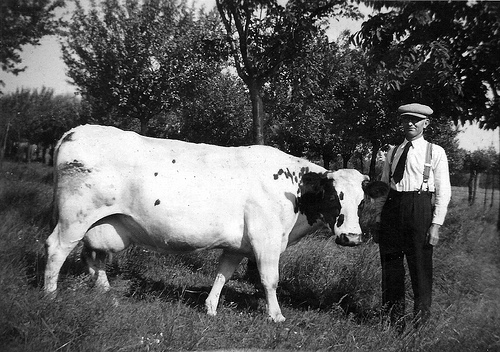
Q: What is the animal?
A: Cow.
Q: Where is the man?
A: Right of the cow.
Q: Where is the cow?
A: Left of the man.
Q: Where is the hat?
A: Man's head.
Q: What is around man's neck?
A: Black tie.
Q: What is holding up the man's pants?
A: Suspenders.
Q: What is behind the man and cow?
A: Orchard.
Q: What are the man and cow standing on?
A: Grass.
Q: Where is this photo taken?
A: Pasture.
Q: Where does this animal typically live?
A: Farm.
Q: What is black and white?
A: Cow.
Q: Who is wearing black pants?
A: The man.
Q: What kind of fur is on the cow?
A: White.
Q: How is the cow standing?
A: Four legs.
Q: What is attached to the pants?
A: Overalls.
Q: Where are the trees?
A: Behind the cow.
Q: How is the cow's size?
A: Big.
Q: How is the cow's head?
A: Black and white.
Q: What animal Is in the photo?
A: A cow.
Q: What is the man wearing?
A: Black pants.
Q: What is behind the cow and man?
A: Trees.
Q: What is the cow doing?
A: Standing.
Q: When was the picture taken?
A: During the day.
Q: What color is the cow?
A: White.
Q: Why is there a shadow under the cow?
A: The sun is directly above the cow.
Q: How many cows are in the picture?
A: One.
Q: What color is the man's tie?
A: Black.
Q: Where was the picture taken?
A: In pasture.